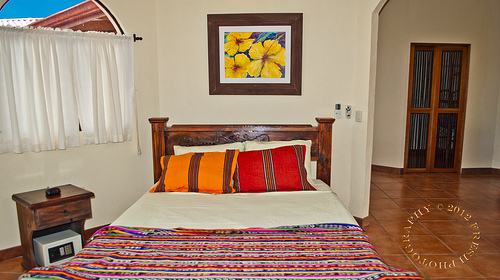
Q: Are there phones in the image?
A: No, there are no phones.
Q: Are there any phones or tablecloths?
A: No, there are no phones or tablecloths.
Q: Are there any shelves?
A: No, there are no shelves.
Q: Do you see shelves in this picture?
A: No, there are no shelves.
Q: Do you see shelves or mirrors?
A: No, there are no shelves or mirrors.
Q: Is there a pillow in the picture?
A: Yes, there is a pillow.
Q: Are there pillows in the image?
A: Yes, there is a pillow.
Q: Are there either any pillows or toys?
A: Yes, there is a pillow.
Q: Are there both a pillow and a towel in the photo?
A: No, there is a pillow but no towels.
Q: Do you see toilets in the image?
A: No, there are no toilets.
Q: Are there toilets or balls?
A: No, there are no toilets or balls.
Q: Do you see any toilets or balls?
A: No, there are no toilets or balls.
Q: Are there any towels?
A: No, there are no towels.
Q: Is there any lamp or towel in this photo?
A: No, there are no towels or lamps.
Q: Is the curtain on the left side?
A: Yes, the curtain is on the left of the image.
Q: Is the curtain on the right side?
A: No, the curtain is on the left of the image.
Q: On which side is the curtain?
A: The curtain is on the left of the image.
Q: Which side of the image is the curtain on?
A: The curtain is on the left of the image.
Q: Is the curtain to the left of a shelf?
A: No, the curtain is to the left of the pillow.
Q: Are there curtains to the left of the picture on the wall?
A: Yes, there is a curtain to the left of the picture.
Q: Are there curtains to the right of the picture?
A: No, the curtain is to the left of the picture.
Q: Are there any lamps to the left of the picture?
A: No, there is a curtain to the left of the picture.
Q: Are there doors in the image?
A: Yes, there is a door.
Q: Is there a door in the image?
A: Yes, there is a door.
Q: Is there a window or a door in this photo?
A: Yes, there is a door.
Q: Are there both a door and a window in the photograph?
A: Yes, there are both a door and a window.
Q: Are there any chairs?
A: No, there are no chairs.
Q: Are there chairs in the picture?
A: No, there are no chairs.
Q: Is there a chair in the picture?
A: No, there are no chairs.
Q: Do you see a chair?
A: No, there are no chairs.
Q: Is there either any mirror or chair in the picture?
A: No, there are no chairs or mirrors.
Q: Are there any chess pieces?
A: No, there are no chess pieces.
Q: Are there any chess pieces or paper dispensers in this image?
A: No, there are no chess pieces or paper dispensers.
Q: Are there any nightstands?
A: Yes, there is a nightstand.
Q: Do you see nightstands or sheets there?
A: Yes, there is a nightstand.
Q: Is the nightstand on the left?
A: Yes, the nightstand is on the left of the image.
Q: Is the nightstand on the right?
A: No, the nightstand is on the left of the image.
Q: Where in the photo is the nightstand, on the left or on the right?
A: The nightstand is on the left of the image.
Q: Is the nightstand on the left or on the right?
A: The nightstand is on the left of the image.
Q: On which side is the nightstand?
A: The nightstand is on the left of the image.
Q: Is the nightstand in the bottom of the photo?
A: Yes, the nightstand is in the bottom of the image.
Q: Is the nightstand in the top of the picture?
A: No, the nightstand is in the bottom of the image.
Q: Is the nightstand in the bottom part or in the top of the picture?
A: The nightstand is in the bottom of the image.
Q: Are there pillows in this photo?
A: Yes, there is a pillow.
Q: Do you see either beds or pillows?
A: Yes, there is a pillow.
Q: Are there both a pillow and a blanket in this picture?
A: Yes, there are both a pillow and a blanket.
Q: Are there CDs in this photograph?
A: No, there are no cds.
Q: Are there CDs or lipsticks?
A: No, there are no CDs or lipsticks.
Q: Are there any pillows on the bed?
A: Yes, there is a pillow on the bed.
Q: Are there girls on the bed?
A: No, there is a pillow on the bed.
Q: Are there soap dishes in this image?
A: No, there are no soap dishes.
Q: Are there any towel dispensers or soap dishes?
A: No, there are no soap dishes or towel dispensers.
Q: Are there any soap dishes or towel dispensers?
A: No, there are no soap dishes or towel dispensers.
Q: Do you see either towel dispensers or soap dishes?
A: No, there are no soap dishes or towel dispensers.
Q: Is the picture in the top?
A: Yes, the picture is in the top of the image.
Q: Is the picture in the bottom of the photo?
A: No, the picture is in the top of the image.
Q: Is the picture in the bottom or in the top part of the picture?
A: The picture is in the top of the image.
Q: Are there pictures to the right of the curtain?
A: Yes, there is a picture to the right of the curtain.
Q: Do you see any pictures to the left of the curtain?
A: No, the picture is to the right of the curtain.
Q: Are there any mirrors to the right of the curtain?
A: No, there is a picture to the right of the curtain.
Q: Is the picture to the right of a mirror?
A: No, the picture is to the right of the curtain.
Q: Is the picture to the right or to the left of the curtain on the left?
A: The picture is to the right of the curtain.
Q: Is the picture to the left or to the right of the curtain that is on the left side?
A: The picture is to the right of the curtain.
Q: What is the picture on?
A: The picture is on the wall.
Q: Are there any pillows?
A: Yes, there is a pillow.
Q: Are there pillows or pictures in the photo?
A: Yes, there is a pillow.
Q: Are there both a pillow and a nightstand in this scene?
A: Yes, there are both a pillow and a nightstand.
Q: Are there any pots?
A: No, there are no pots.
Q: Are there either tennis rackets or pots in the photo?
A: No, there are no pots or tennis rackets.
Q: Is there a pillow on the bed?
A: Yes, there is a pillow on the bed.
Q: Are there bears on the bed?
A: No, there is a pillow on the bed.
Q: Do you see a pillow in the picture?
A: Yes, there is a pillow.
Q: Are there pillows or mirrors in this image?
A: Yes, there is a pillow.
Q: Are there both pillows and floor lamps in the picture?
A: No, there is a pillow but no floor lamps.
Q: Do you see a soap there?
A: No, there are no soaps.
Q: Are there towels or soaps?
A: No, there are no soaps or towels.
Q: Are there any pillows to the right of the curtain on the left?
A: Yes, there is a pillow to the right of the curtain.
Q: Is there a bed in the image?
A: Yes, there is a bed.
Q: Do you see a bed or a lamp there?
A: Yes, there is a bed.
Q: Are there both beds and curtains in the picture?
A: Yes, there are both a bed and a curtain.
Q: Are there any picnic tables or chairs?
A: No, there are no chairs or picnic tables.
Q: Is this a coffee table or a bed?
A: This is a bed.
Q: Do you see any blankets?
A: Yes, there is a blanket.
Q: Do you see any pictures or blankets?
A: Yes, there is a blanket.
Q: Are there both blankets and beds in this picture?
A: Yes, there are both a blanket and a bed.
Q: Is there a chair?
A: No, there are no chairs.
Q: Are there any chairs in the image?
A: No, there are no chairs.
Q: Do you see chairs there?
A: No, there are no chairs.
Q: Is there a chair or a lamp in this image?
A: No, there are no chairs or lamps.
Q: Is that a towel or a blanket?
A: That is a blanket.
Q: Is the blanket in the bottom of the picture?
A: Yes, the blanket is in the bottom of the image.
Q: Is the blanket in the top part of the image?
A: No, the blanket is in the bottom of the image.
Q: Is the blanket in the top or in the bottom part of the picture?
A: The blanket is in the bottom of the image.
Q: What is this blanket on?
A: The blanket is on the bed.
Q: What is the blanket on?
A: The blanket is on the bed.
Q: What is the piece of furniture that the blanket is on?
A: The piece of furniture is a bed.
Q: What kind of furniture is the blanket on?
A: The blanket is on the bed.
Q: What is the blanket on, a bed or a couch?
A: The blanket is on a bed.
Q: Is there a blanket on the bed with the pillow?
A: Yes, there is a blanket on the bed.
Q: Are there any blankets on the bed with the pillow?
A: Yes, there is a blanket on the bed.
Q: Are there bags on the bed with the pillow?
A: No, there is a blanket on the bed.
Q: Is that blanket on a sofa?
A: No, the blanket is on a bed.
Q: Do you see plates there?
A: Yes, there is a plate.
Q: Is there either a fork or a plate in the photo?
A: Yes, there is a plate.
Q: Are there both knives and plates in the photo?
A: No, there is a plate but no knives.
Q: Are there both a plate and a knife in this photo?
A: No, there is a plate but no knives.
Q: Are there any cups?
A: No, there are no cups.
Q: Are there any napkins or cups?
A: No, there are no cups or napkins.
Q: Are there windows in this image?
A: Yes, there is a window.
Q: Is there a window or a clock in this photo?
A: Yes, there is a window.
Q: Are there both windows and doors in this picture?
A: Yes, there are both a window and a door.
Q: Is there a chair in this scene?
A: No, there are no chairs.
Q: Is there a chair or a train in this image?
A: No, there are no chairs or trains.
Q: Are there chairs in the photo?
A: No, there are no chairs.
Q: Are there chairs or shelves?
A: No, there are no chairs or shelves.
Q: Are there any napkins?
A: No, there are no napkins.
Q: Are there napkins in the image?
A: No, there are no napkins.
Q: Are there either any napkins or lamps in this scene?
A: No, there are no napkins or lamps.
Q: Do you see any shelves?
A: No, there are no shelves.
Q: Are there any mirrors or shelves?
A: No, there are no shelves or mirrors.